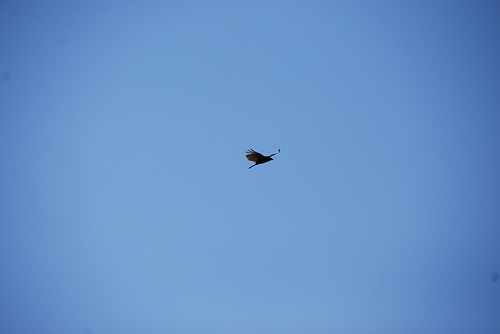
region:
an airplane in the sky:
[189, 114, 311, 195]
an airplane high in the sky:
[182, 112, 312, 187]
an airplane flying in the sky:
[200, 120, 311, 192]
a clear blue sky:
[18, 163, 220, 331]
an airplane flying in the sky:
[218, 95, 335, 210]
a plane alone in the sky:
[200, 79, 321, 200]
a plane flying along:
[162, 113, 311, 196]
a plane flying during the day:
[193, 112, 313, 199]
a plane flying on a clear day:
[210, 100, 356, 192]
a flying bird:
[206, 118, 313, 211]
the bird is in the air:
[207, 113, 329, 214]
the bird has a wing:
[236, 136, 296, 177]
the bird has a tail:
[261, 133, 286, 168]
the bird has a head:
[246, 155, 257, 174]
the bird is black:
[227, 116, 307, 192]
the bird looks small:
[213, 111, 322, 228]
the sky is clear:
[1, 6, 494, 328]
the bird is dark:
[216, 125, 299, 206]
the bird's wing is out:
[238, 137, 295, 179]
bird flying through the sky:
[227, 139, 348, 199]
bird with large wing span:
[218, 130, 296, 187]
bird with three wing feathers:
[216, 115, 298, 191]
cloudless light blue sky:
[128, 134, 210, 279]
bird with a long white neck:
[223, 125, 306, 202]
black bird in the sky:
[226, 130, 297, 201]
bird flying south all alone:
[216, 110, 302, 187]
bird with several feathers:
[231, 138, 311, 201]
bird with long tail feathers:
[223, 133, 289, 196]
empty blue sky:
[323, 83, 416, 256]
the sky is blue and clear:
[65, 13, 172, 268]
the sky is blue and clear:
[27, 54, 186, 318]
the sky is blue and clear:
[102, 105, 287, 330]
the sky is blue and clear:
[92, 156, 214, 323]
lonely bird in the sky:
[221, 115, 320, 212]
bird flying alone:
[225, 113, 317, 183]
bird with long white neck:
[204, 122, 301, 184]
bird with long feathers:
[226, 119, 313, 197]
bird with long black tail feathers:
[203, 116, 320, 201]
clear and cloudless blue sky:
[99, 132, 169, 269]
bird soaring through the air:
[225, 124, 297, 184]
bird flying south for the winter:
[211, 109, 303, 195]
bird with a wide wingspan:
[212, 127, 299, 194]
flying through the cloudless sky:
[222, 107, 304, 201]